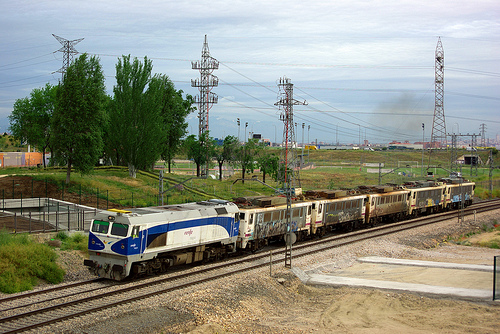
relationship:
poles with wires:
[50, 31, 488, 258] [0, 51, 499, 149]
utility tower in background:
[431, 34, 454, 151] [1, 0, 500, 160]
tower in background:
[428, 33, 450, 143] [1, 0, 500, 160]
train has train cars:
[83, 175, 476, 280] [236, 179, 482, 249]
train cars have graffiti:
[236, 179, 482, 249] [252, 194, 480, 242]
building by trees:
[0, 149, 52, 170] [12, 54, 199, 173]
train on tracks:
[83, 175, 476, 280] [0, 197, 499, 331]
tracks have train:
[0, 197, 499, 331] [83, 175, 476, 280]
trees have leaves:
[12, 54, 199, 173] [14, 101, 52, 121]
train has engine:
[83, 175, 476, 280] [84, 196, 240, 278]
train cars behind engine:
[236, 179, 482, 249] [84, 196, 240, 278]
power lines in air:
[4, 47, 498, 155] [2, 1, 499, 163]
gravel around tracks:
[0, 201, 498, 332] [0, 197, 499, 331]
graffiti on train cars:
[252, 194, 480, 242] [236, 179, 482, 249]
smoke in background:
[367, 89, 437, 142] [1, 0, 500, 160]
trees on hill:
[12, 54, 199, 173] [0, 162, 267, 207]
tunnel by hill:
[3, 193, 117, 229] [0, 162, 267, 207]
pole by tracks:
[288, 180, 294, 268] [0, 197, 499, 331]